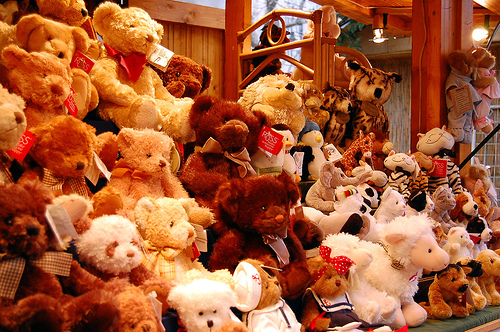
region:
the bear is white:
[179, 276, 229, 329]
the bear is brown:
[218, 168, 298, 243]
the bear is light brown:
[114, 134, 165, 184]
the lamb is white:
[369, 219, 436, 316]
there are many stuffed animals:
[7, 17, 474, 305]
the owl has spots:
[338, 56, 405, 127]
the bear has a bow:
[298, 249, 348, 324]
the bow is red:
[318, 246, 357, 266]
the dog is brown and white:
[455, 188, 478, 218]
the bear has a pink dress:
[475, 49, 493, 112]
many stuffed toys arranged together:
[0, 1, 499, 329]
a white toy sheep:
[323, 212, 449, 327]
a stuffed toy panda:
[73, 212, 143, 279]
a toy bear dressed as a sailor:
[230, 255, 305, 327]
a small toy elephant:
[305, 160, 370, 210]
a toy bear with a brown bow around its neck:
[105, 125, 185, 205]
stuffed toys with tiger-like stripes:
[381, 122, 457, 192]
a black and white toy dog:
[465, 215, 490, 250]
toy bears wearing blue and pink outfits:
[445, 43, 497, 140]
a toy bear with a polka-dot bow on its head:
[303, 246, 363, 330]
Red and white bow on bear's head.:
[313, 245, 352, 276]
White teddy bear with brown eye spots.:
[73, 212, 140, 280]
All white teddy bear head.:
[165, 280, 247, 328]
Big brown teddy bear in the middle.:
[225, 162, 303, 279]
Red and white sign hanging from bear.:
[253, 122, 278, 155]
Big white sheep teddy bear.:
[373, 214, 438, 310]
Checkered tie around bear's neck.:
[5, 244, 27, 306]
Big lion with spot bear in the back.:
[351, 54, 389, 148]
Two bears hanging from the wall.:
[456, 27, 498, 114]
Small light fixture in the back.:
[361, 10, 389, 50]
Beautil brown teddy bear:
[93, 9, 170, 119]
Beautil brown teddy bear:
[217, 180, 307, 275]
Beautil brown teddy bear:
[186, 94, 245, 188]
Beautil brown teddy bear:
[5, 185, 62, 307]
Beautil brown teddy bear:
[47, 116, 94, 180]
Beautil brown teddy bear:
[12, 35, 79, 129]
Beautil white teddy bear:
[374, 211, 431, 327]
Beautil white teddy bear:
[170, 271, 247, 329]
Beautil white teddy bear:
[376, 184, 405, 216]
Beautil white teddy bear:
[450, 221, 472, 258]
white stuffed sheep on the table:
[321, 214, 444, 321]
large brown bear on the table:
[213, 170, 320, 298]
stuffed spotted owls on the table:
[319, 58, 401, 143]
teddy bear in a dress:
[303, 250, 390, 330]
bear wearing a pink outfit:
[467, 48, 499, 140]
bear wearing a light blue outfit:
[438, 52, 480, 145]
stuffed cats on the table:
[383, 125, 460, 201]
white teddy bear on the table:
[168, 273, 243, 328]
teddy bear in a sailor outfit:
[231, 256, 305, 330]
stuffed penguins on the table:
[265, 118, 330, 176]